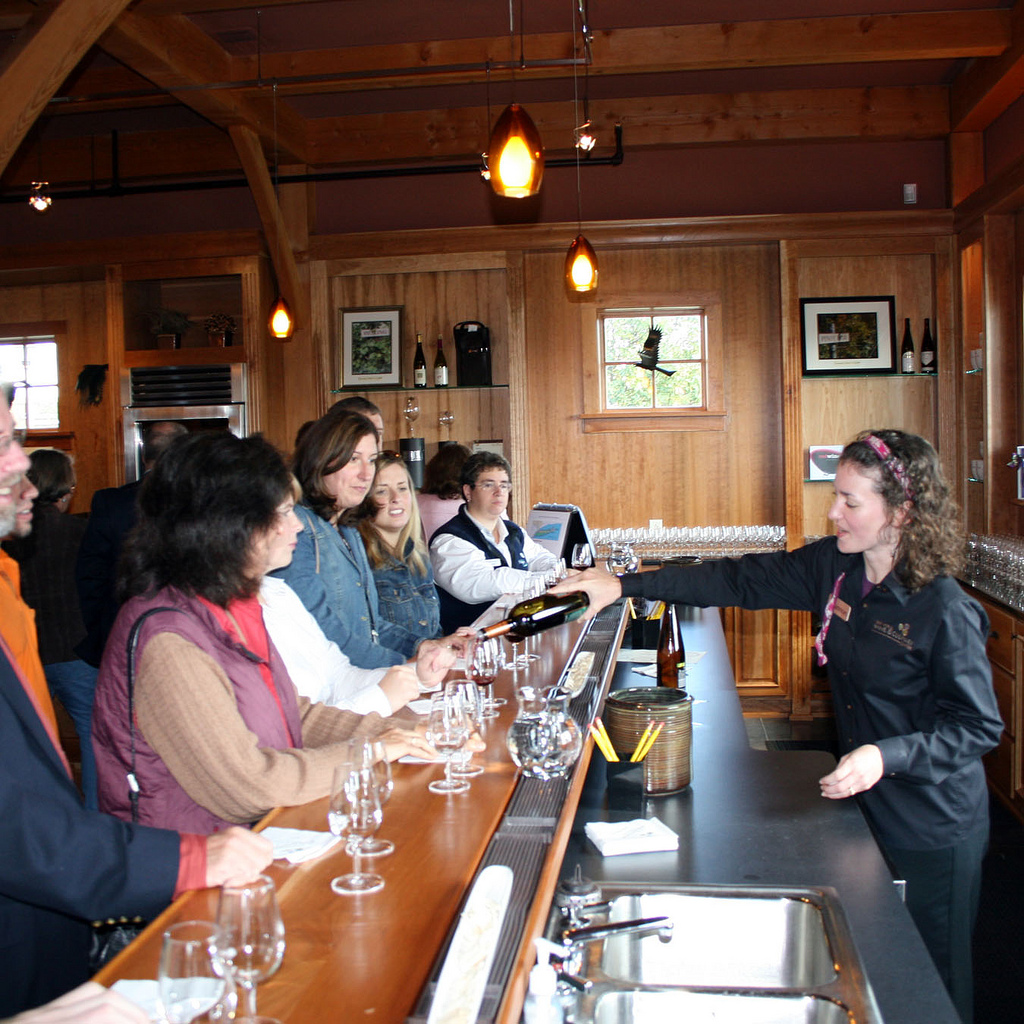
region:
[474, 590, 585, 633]
A bottle of wine being poured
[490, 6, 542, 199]
A hanging pendant lamp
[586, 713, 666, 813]
A container filled with pencils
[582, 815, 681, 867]
A stack of napkins on the counter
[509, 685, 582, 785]
A pitcher filled with water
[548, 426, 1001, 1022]
A woman pouring a bottle of wine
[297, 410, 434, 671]
Two women watching wine being poured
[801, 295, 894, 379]
A framed picture hanging on the wall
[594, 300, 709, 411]
A window with something sticking on it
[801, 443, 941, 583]
the head of a young woman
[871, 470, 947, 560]
the ear of a young woman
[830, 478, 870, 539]
the eye of a young woman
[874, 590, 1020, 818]
the arm of a young woman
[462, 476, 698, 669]
a woman holding a bottle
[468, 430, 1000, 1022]
the bartender is pouring a drink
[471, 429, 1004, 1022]
the bartender is holding a bottle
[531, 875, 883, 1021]
the double sink is made of metal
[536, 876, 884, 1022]
the double sink silver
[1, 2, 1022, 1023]
the people at the bar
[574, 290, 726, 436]
the window is small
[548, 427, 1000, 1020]
the bartender has brown hair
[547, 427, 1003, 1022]
the bartender has curly hair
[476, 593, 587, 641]
the bottle is green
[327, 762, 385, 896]
the wine glass is clear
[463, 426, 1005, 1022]
bartender is pouring red wine into a glass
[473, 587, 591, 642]
bottle of red wine is being poured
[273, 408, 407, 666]
woman is standing at a bar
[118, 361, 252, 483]
fireplace in the wall by a bar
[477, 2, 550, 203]
light hanging down from the ceiling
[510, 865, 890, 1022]
silver sink behind the bar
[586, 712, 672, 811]
black box filled with pencils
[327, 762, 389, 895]
wine glass sitting on the bar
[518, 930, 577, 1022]
hand soap on the kitchen sink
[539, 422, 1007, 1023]
the bartender is a woman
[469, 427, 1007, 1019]
the bartender pours a glass of wine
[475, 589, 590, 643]
the wine bottle is green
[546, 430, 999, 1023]
the bartender is dressed in black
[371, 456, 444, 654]
a blonde woman wears a denim jacket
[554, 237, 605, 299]
a light hangs from the ceiling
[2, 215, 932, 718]
the walls are wood paneled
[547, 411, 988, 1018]
a person is standing up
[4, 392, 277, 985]
a person is sitting down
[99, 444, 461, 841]
a person is sitting down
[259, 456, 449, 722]
a person is sitting down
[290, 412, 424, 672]
a person is sitting down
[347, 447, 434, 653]
a person is sitting down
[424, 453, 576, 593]
a person is sitting down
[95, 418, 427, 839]
Woman with black hair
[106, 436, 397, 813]
Woman sitting at bar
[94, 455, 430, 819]
Woman in pink vest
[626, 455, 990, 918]
Woman in black shirt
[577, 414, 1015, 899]
Woman pouring people drinks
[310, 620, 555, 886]
Glasses on the bar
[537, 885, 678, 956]
Faucet on the sink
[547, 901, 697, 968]
Silver faucet on silver sink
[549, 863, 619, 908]
Drain on the sink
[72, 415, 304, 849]
woman wearing purple vest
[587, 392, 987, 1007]
woman pouring the wine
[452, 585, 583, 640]
bottle of wine being poured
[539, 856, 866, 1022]
double basin sink in the counter